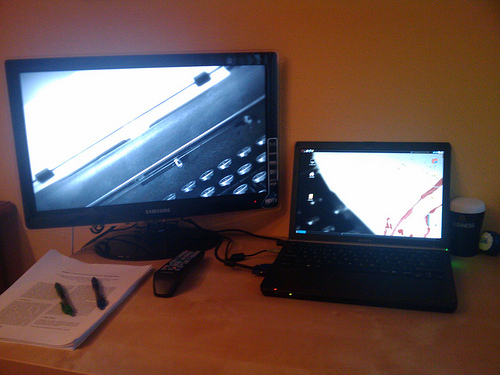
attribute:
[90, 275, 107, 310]
pen — black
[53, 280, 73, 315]
pen — black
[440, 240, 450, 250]
light — small, green, colored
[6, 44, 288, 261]
monitor — flat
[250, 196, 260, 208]
red light — small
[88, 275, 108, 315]
pen — black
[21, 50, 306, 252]
monitor — black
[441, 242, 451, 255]
light — small, green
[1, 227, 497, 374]
desk — brown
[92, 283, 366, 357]
table — brown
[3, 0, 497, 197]
wall — yellow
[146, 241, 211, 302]
mouse — black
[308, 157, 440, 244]
typewriter — old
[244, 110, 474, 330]
laptop — black